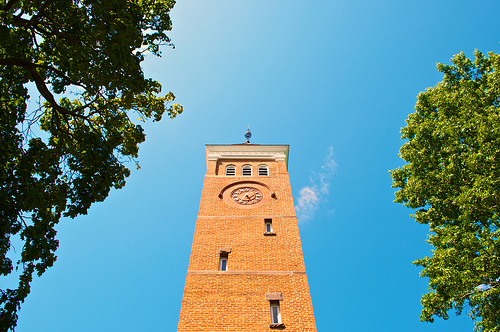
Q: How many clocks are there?
A: One.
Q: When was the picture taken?
A: Daytime.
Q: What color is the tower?
A: Red.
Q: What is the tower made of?
A: Brick.